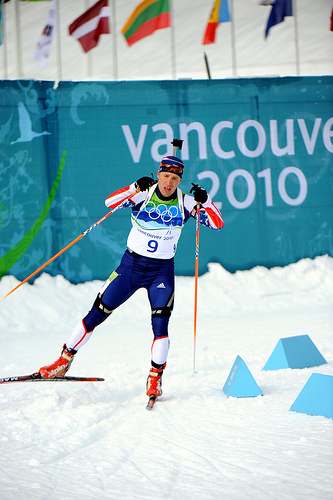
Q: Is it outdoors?
A: Yes, it is outdoors.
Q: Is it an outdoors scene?
A: Yes, it is outdoors.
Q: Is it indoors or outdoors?
A: It is outdoors.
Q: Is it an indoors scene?
A: No, it is outdoors.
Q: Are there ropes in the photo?
A: No, there are no ropes.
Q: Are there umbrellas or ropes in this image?
A: No, there are no ropes or umbrellas.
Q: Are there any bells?
A: No, there are no bells.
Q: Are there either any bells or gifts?
A: No, there are no bells or gifts.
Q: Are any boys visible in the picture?
A: No, there are no boys.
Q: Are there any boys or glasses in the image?
A: No, there are no boys or glasses.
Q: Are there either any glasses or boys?
A: No, there are no boys or glasses.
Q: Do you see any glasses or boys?
A: No, there are no boys or glasses.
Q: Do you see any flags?
A: Yes, there is a flag.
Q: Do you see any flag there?
A: Yes, there is a flag.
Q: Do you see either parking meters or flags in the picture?
A: Yes, there is a flag.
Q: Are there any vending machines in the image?
A: No, there are no vending machines.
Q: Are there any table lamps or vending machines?
A: No, there are no vending machines or table lamps.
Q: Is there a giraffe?
A: No, there are no giraffes.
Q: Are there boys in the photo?
A: No, there are no boys.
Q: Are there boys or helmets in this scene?
A: No, there are no boys or helmets.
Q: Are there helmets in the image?
A: No, there are no helmets.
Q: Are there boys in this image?
A: No, there are no boys.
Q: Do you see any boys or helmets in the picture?
A: No, there are no boys or helmets.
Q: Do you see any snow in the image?
A: Yes, there is snow.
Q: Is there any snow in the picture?
A: Yes, there is snow.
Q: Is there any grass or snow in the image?
A: Yes, there is snow.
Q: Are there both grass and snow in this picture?
A: No, there is snow but no grass.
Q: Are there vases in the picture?
A: No, there are no vases.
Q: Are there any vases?
A: No, there are no vases.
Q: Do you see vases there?
A: No, there are no vases.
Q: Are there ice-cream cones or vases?
A: No, there are no vases or ice-cream cones.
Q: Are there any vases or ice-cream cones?
A: No, there are no vases or ice-cream cones.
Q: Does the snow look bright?
A: Yes, the snow is bright.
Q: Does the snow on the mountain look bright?
A: Yes, the snow is bright.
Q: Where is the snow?
A: The snow is on the mountain.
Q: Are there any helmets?
A: No, there are no helmets.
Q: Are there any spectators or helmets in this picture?
A: No, there are no helmets or spectators.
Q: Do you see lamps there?
A: No, there are no lamps.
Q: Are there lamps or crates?
A: No, there are no lamps or crates.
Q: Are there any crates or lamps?
A: No, there are no lamps or crates.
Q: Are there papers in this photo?
A: No, there are no papers.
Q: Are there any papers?
A: No, there are no papers.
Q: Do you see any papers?
A: No, there are no papers.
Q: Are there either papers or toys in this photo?
A: No, there are no papers or toys.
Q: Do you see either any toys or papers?
A: No, there are no papers or toys.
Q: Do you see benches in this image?
A: No, there are no benches.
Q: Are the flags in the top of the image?
A: Yes, the flags are in the top of the image.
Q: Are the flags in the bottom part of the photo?
A: No, the flags are in the top of the image.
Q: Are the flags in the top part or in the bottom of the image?
A: The flags are in the top of the image.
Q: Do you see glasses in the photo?
A: No, there are no glasses.